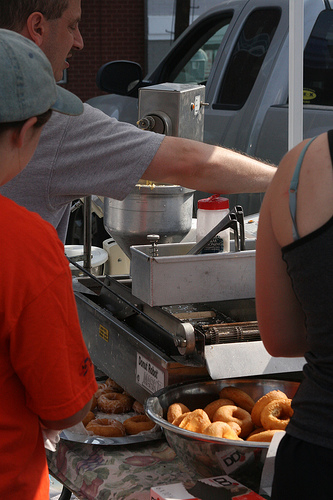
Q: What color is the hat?
A: Gray.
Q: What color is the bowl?
A: Silver.